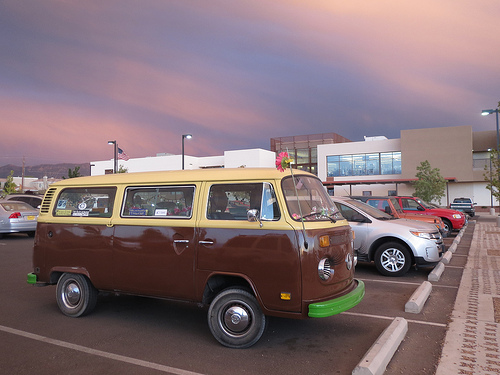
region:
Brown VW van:
[26, 162, 366, 349]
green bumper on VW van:
[306, 272, 367, 319]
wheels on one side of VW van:
[54, 267, 266, 349]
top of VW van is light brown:
[34, 168, 351, 230]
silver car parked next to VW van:
[327, 191, 447, 283]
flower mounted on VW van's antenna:
[273, 148, 296, 173]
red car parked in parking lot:
[389, 190, 466, 235]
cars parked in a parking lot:
[0, 163, 482, 373]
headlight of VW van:
[316, 255, 338, 282]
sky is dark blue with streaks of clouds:
[2, 0, 497, 162]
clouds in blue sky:
[4, 2, 496, 162]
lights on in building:
[325, 150, 402, 176]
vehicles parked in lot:
[3, 168, 473, 348]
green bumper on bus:
[306, 279, 365, 319]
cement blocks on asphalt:
[351, 222, 466, 373]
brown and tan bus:
[28, 167, 363, 316]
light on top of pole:
[180, 133, 192, 167]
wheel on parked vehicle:
[372, 239, 410, 277]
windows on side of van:
[52, 182, 277, 222]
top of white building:
[91, 149, 278, 174]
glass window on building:
[324, 154, 339, 176]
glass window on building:
[336, 155, 351, 174]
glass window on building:
[352, 154, 365, 176]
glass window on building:
[367, 155, 381, 175]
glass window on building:
[379, 151, 391, 173]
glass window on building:
[391, 153, 401, 175]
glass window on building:
[290, 150, 296, 163]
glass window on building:
[295, 149, 310, 161]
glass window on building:
[309, 146, 315, 165]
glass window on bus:
[123, 187, 195, 219]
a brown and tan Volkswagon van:
[33, 166, 362, 349]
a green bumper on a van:
[307, 273, 367, 320]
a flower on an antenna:
[271, 150, 293, 174]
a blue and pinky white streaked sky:
[0, 0, 498, 164]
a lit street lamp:
[178, 127, 196, 170]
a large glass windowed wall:
[321, 148, 404, 180]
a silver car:
[0, 198, 40, 235]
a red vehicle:
[392, 191, 469, 230]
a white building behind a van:
[87, 143, 277, 179]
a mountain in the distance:
[4, 159, 90, 180]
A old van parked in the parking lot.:
[26, 143, 351, 344]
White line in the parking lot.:
[16, 308, 133, 368]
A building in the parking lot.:
[241, 123, 491, 200]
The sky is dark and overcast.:
[74, 27, 391, 119]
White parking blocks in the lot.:
[391, 268, 442, 319]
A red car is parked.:
[393, 197, 479, 237]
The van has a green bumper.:
[287, 299, 375, 313]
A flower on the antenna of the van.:
[266, 141, 301, 178]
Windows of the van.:
[71, 181, 223, 222]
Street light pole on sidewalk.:
[451, 96, 498, 192]